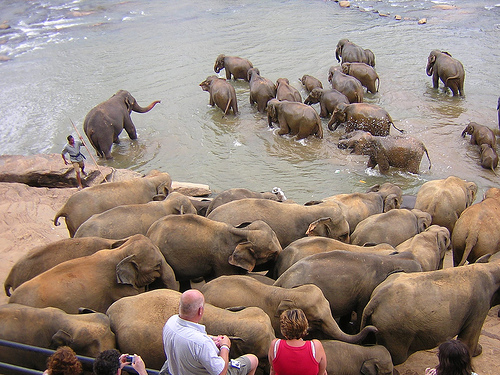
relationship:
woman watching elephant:
[267, 308, 327, 374] [82, 89, 161, 160]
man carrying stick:
[62, 134, 88, 189] [68, 117, 108, 184]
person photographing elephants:
[95, 348, 148, 374] [4, 170, 499, 373]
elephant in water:
[82, 89, 161, 160] [1, 1, 498, 202]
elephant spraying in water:
[338, 131, 431, 175] [1, 1, 498, 202]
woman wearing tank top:
[267, 308, 327, 374] [271, 338, 321, 374]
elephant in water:
[426, 48, 465, 97] [1, 1, 498, 202]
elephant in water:
[338, 131, 431, 175] [1, 1, 498, 202]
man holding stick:
[62, 134, 88, 189] [68, 117, 108, 184]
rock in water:
[418, 18, 427, 24] [1, 1, 498, 202]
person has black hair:
[95, 348, 148, 374] [92, 348, 121, 374]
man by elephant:
[62, 134, 88, 189] [82, 89, 161, 160]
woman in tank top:
[267, 308, 327, 374] [271, 338, 321, 374]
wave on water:
[17, 21, 80, 34] [1, 1, 498, 202]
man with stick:
[62, 134, 88, 189] [68, 117, 108, 184]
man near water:
[62, 134, 88, 189] [1, 1, 498, 202]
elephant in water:
[200, 75, 239, 118] [1, 1, 498, 202]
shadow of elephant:
[99, 137, 145, 169] [82, 89, 161, 160]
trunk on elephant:
[134, 101, 161, 112] [82, 89, 161, 160]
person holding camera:
[95, 348, 148, 374] [125, 355, 134, 365]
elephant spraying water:
[338, 131, 431, 175] [1, 1, 498, 202]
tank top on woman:
[271, 338, 321, 374] [267, 308, 327, 374]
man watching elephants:
[163, 288, 259, 374] [4, 170, 499, 373]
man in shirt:
[163, 288, 259, 374] [163, 313, 225, 374]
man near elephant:
[62, 134, 88, 189] [82, 89, 161, 160]